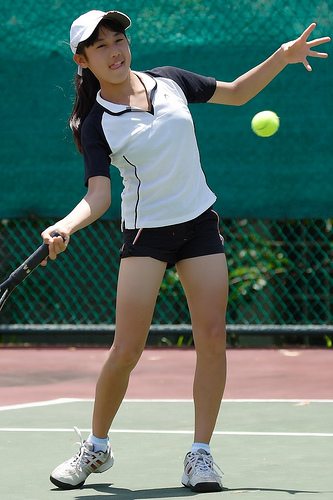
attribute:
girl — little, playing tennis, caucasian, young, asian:
[40, 9, 331, 488]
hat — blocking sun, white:
[69, 10, 131, 50]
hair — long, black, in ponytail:
[66, 19, 130, 153]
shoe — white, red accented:
[50, 446, 115, 492]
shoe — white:
[180, 450, 220, 491]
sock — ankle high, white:
[89, 432, 110, 450]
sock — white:
[191, 438, 212, 454]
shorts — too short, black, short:
[119, 211, 226, 261]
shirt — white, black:
[76, 62, 217, 229]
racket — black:
[0, 229, 67, 322]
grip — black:
[12, 228, 62, 284]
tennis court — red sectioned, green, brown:
[2, 343, 330, 499]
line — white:
[1, 423, 332, 440]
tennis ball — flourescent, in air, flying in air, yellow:
[251, 110, 281, 138]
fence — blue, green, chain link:
[2, 2, 332, 346]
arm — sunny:
[150, 49, 288, 112]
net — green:
[0, 4, 332, 224]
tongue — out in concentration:
[110, 62, 123, 71]